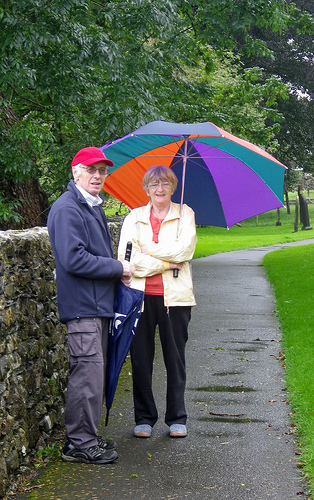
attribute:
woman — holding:
[113, 160, 197, 437]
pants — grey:
[65, 318, 106, 450]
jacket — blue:
[45, 181, 126, 326]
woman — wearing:
[90, 161, 211, 277]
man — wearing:
[39, 145, 134, 464]